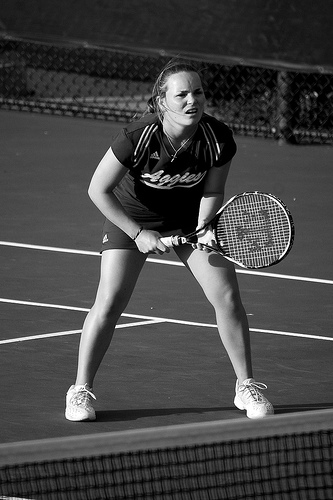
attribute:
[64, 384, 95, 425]
tennis shoe — white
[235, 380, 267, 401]
laces — white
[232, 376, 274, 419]
shoe — white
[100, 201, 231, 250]
shorts — dark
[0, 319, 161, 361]
line — white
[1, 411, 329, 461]
trim — white